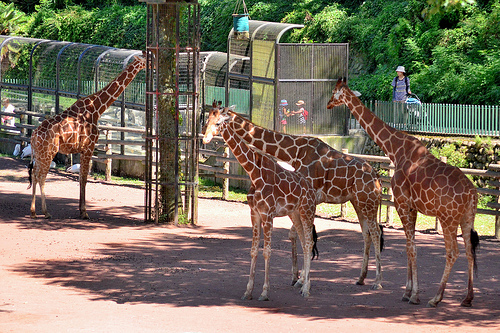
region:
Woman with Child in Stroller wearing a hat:
[386, 57, 432, 140]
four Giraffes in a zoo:
[21, 42, 488, 312]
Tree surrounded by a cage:
[141, 0, 202, 205]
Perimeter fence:
[215, 15, 383, 153]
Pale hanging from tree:
[225, 2, 255, 39]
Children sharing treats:
[271, 90, 311, 135]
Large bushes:
[318, 0, 496, 76]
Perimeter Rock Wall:
[413, 130, 493, 195]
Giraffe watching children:
[16, 42, 152, 232]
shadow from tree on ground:
[57, 219, 320, 320]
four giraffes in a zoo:
[54, 35, 486, 282]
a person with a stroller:
[369, 50, 444, 149]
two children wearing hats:
[248, 69, 356, 164]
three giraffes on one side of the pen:
[191, 68, 484, 298]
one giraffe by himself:
[14, 55, 184, 218]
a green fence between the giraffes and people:
[341, 65, 497, 175]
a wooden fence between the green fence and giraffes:
[13, 98, 416, 202]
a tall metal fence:
[6, 30, 270, 156]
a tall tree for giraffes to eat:
[111, 0, 206, 254]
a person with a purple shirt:
[375, 62, 457, 157]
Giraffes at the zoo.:
[172, 66, 483, 285]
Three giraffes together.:
[185, 57, 497, 254]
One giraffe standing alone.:
[27, 62, 197, 234]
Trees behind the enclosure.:
[271, 17, 446, 114]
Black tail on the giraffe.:
[463, 222, 488, 265]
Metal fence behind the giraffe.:
[30, 25, 143, 104]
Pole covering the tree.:
[135, 5, 225, 251]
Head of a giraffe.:
[319, 70, 380, 147]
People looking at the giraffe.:
[373, 50, 472, 159]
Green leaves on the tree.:
[383, 17, 488, 92]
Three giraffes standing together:
[198, 80, 480, 313]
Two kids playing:
[253, 75, 328, 139]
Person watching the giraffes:
[331, 54, 491, 308]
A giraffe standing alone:
[17, 46, 162, 221]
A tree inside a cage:
[117, 0, 207, 228]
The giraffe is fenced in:
[1, 27, 222, 208]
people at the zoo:
[263, 57, 447, 154]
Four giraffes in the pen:
[23, 52, 483, 312]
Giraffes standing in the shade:
[188, 100, 482, 331]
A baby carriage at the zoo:
[378, 57, 436, 132]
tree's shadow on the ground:
[30, 211, 332, 323]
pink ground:
[18, 218, 116, 311]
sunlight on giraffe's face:
[191, 96, 320, 206]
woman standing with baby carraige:
[372, 47, 439, 120]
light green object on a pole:
[203, 2, 285, 47]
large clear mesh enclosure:
[28, 27, 288, 137]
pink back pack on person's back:
[296, 106, 322, 126]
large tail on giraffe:
[284, 197, 345, 256]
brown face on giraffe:
[185, 114, 248, 165]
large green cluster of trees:
[53, 9, 488, 99]